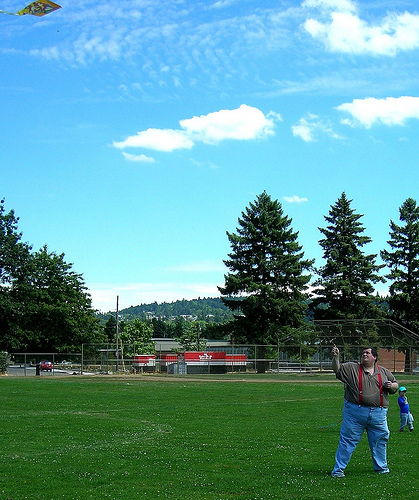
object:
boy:
[331, 343, 401, 483]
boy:
[398, 387, 414, 434]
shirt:
[397, 395, 410, 413]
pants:
[400, 412, 413, 430]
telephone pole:
[115, 292, 119, 370]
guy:
[332, 347, 396, 478]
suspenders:
[357, 364, 364, 406]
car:
[39, 361, 52, 372]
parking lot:
[6, 365, 79, 379]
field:
[2, 375, 416, 499]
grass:
[3, 376, 418, 499]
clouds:
[115, 104, 274, 152]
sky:
[1, 1, 418, 303]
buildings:
[136, 351, 211, 373]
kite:
[11, 1, 61, 19]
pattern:
[18, 0, 62, 16]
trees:
[313, 192, 383, 343]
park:
[3, 192, 417, 490]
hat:
[400, 387, 406, 390]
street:
[9, 352, 84, 380]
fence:
[6, 343, 418, 374]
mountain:
[105, 297, 220, 321]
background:
[2, 242, 417, 343]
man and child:
[327, 343, 419, 487]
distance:
[4, 309, 417, 382]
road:
[4, 363, 67, 375]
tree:
[218, 192, 316, 372]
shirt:
[336, 359, 395, 407]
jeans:
[327, 405, 401, 478]